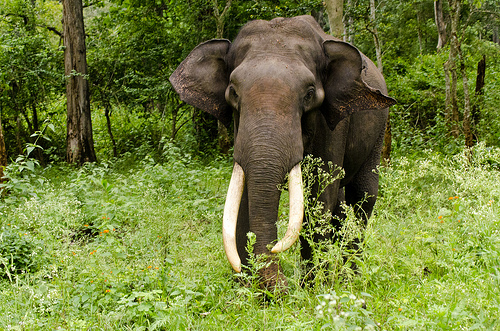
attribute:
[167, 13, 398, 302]
elephant — large, gray, a bull, walking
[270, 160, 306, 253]
tusk — white, long, ivory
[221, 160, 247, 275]
tusk — white, long, ivory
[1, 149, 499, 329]
brush — filling area, grassy, tall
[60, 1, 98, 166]
trunk — left of elephant, brown, tall, wood, bare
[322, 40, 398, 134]
ear — flapping, large, floppy, gray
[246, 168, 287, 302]
trunk — strong, efficient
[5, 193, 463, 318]
flowers — small, orange, yellow, wild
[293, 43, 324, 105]
temples — sunken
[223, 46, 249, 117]
temple — sunken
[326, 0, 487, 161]
trunks — right of elephant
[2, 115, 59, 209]
leaves — green, top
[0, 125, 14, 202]
stump — dead, broken, rotted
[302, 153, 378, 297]
plant — growing, tall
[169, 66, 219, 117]
spots — brown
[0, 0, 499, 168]
area — wooded, lush, green, thick